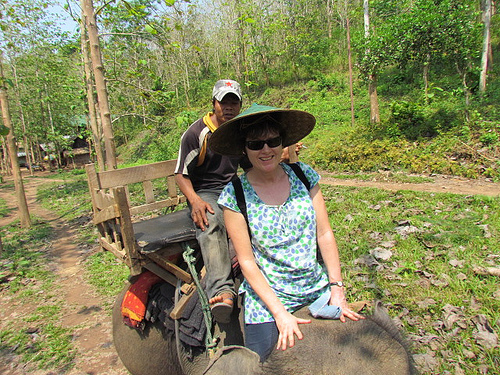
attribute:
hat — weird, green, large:
[207, 101, 318, 159]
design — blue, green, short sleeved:
[216, 161, 336, 325]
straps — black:
[225, 160, 311, 228]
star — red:
[223, 80, 234, 90]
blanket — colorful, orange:
[120, 266, 172, 332]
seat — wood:
[80, 160, 200, 280]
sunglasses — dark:
[245, 136, 284, 151]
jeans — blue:
[242, 315, 284, 365]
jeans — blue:
[186, 185, 239, 296]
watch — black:
[326, 279, 347, 289]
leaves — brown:
[341, 190, 498, 370]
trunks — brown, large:
[74, 0, 121, 172]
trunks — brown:
[339, 0, 383, 129]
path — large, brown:
[9, 172, 129, 375]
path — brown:
[311, 165, 499, 202]